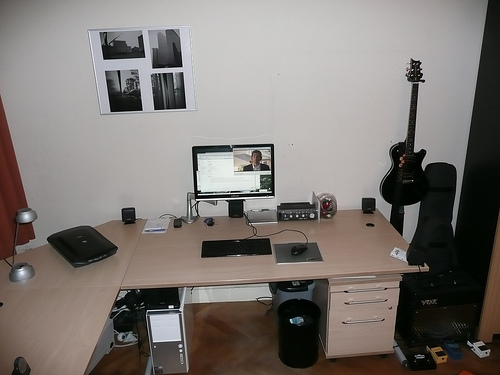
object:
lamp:
[11, 207, 38, 265]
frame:
[86, 24, 198, 116]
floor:
[188, 303, 252, 374]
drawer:
[312, 273, 401, 360]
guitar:
[377, 57, 430, 207]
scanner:
[45, 224, 118, 268]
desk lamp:
[0, 257, 36, 284]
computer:
[144, 286, 192, 375]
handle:
[344, 296, 389, 306]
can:
[274, 297, 323, 369]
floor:
[327, 357, 398, 374]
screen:
[190, 142, 277, 202]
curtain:
[0, 94, 35, 261]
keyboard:
[200, 238, 272, 259]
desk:
[0, 207, 431, 375]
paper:
[288, 314, 305, 325]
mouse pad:
[272, 241, 324, 265]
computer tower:
[178, 286, 187, 311]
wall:
[0, 0, 488, 245]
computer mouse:
[290, 244, 309, 256]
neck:
[405, 82, 419, 154]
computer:
[179, 143, 276, 225]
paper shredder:
[270, 279, 318, 314]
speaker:
[121, 206, 136, 225]